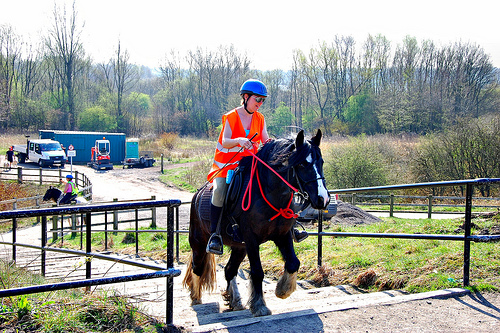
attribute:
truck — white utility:
[9, 137, 69, 168]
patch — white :
[297, 154, 327, 202]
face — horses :
[281, 123, 342, 222]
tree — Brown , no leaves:
[450, 39, 491, 126]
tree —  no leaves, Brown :
[30, 12, 136, 162]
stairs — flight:
[26, 232, 386, 309]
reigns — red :
[242, 145, 302, 221]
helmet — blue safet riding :
[239, 77, 268, 96]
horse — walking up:
[187, 125, 331, 312]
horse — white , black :
[158, 130, 393, 311]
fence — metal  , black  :
[8, 193, 188, 312]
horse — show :
[176, 143, 374, 315]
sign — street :
[64, 143, 79, 168]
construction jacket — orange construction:
[204, 108, 266, 185]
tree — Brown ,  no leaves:
[43, 4, 90, 133]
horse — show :
[184, 127, 337, 320]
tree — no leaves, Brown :
[363, 46, 391, 113]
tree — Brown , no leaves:
[282, 50, 314, 135]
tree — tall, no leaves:
[428, 46, 486, 129]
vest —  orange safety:
[205, 104, 265, 185]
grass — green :
[65, 210, 480, 270]